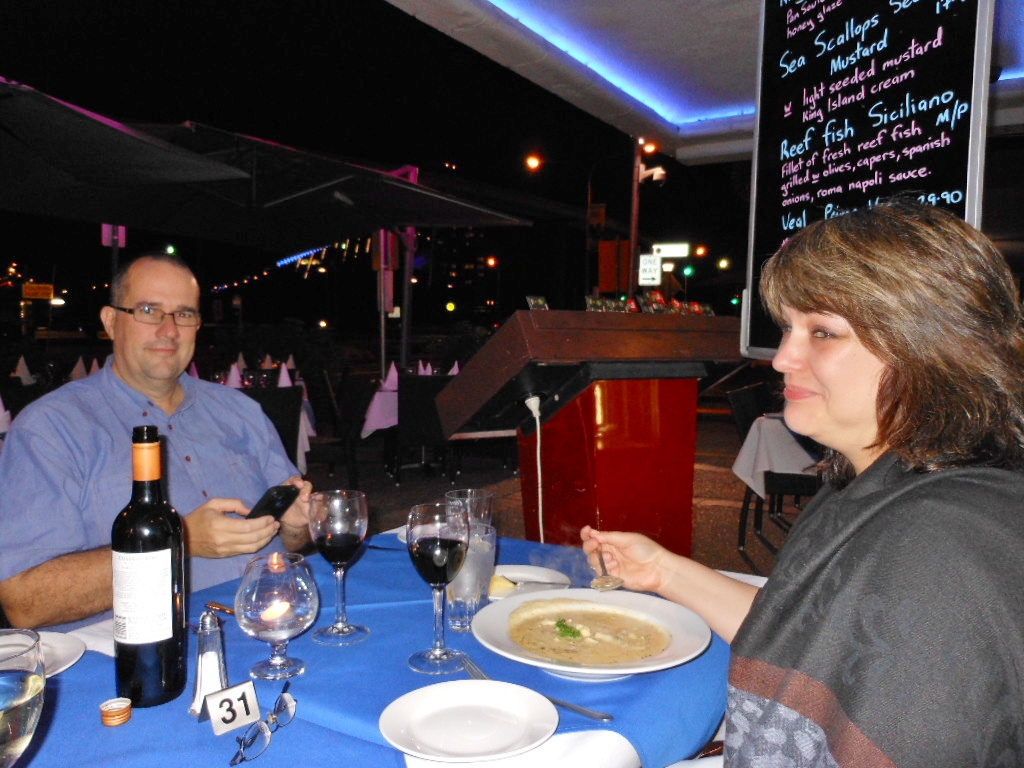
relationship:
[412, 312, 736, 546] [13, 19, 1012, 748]
podium in restaurant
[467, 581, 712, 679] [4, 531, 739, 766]
bowl on table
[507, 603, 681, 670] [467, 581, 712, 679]
soup in bowl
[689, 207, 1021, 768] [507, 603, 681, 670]
lady eating soup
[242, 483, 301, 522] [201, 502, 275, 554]
cell phone in hand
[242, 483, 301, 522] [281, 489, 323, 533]
cell phone in hand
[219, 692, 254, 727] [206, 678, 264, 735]
number on sign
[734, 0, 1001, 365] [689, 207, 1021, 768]
menu board hanging behind lady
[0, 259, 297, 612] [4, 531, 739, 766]
man seated at table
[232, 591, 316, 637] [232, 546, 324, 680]
candle in glass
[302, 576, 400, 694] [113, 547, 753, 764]
tablecloth on table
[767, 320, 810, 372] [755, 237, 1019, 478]
nose of woman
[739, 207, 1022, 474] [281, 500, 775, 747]
lady sitting at table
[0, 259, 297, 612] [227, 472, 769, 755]
man sitting at table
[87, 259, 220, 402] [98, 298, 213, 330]
man wearing eyeglasses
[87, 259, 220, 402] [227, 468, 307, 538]
man holding cell phone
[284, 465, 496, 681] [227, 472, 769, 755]
glasses on table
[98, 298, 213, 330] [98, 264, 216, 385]
eyeglasses on man